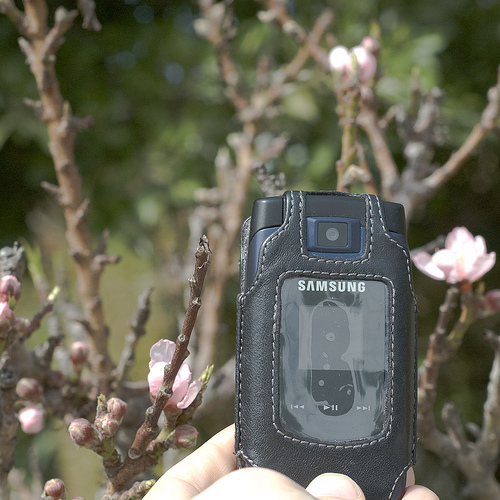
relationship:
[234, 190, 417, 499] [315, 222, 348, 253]
cell phone has camera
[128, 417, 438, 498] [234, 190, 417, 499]
hand holding cell phone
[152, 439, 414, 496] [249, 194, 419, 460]
person holding cellphone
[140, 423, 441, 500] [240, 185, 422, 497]
person holding cell phone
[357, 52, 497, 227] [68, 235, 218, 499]
branch next to branch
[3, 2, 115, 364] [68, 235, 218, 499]
branch next to branch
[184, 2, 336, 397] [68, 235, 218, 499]
branch next to branch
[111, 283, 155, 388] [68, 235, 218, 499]
branch next to branch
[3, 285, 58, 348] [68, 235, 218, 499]
branch next to branch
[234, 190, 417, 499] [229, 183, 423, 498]
cell phone in case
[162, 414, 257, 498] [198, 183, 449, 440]
fingers holding cellphone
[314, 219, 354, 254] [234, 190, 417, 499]
lense on cell phone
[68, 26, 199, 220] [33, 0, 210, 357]
foliage on tree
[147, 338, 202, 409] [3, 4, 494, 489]
flower on background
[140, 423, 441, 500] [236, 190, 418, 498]
person holding cellphone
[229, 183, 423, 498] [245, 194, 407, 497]
case over cellphone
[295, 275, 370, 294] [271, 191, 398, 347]
name on case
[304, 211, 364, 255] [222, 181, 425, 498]
camera of phone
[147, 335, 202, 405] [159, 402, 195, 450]
flower on branch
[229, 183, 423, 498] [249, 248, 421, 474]
case trimmed in thread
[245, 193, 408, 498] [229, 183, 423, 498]
cell phone in a case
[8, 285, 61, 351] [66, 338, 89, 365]
branch with flower buds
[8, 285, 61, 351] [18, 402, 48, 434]
branch with flower buds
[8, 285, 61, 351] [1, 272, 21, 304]
branch with flower buds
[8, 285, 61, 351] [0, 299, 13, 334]
branch with flower buds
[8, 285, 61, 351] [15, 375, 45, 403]
branch with flower buds